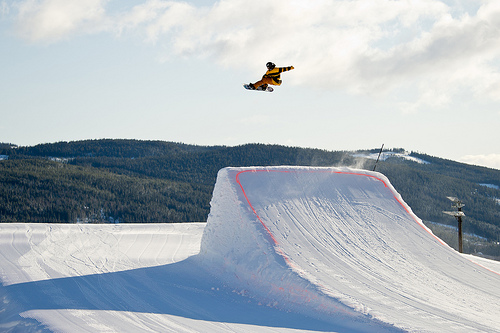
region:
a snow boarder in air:
[241, 60, 294, 91]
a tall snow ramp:
[196, 162, 496, 327]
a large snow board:
[240, 80, 272, 90]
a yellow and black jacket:
[261, 63, 291, 83]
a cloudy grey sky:
[1, 0, 498, 170]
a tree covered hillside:
[0, 139, 499, 259]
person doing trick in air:
[240, 53, 288, 93]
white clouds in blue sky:
[64, 43, 82, 53]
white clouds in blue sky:
[358, 102, 410, 129]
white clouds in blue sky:
[442, 45, 496, 102]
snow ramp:
[225, 162, 455, 317]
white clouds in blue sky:
[141, 18, 185, 53]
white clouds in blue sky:
[138, 72, 173, 96]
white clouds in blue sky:
[362, 29, 403, 66]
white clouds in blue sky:
[54, 81, 76, 88]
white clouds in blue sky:
[112, 56, 147, 86]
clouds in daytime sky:
[0, 1, 499, 165]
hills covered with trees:
[0, 134, 497, 223]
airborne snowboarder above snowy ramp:
[2, 57, 497, 331]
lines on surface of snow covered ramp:
[201, 163, 497, 331]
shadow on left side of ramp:
[3, 166, 492, 329]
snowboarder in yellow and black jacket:
[245, 62, 295, 93]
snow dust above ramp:
[200, 153, 497, 331]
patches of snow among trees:
[364, 145, 497, 254]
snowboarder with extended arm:
[245, 61, 295, 91]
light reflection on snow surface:
[2, 220, 204, 331]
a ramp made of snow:
[207, 160, 494, 328]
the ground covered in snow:
[14, 215, 185, 302]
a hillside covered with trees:
[5, 131, 222, 180]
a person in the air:
[243, 55, 303, 102]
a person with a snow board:
[240, 55, 290, 95]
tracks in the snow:
[23, 218, 159, 292]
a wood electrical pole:
[453, 195, 474, 254]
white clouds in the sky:
[340, 9, 487, 97]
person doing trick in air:
[237, 57, 291, 92]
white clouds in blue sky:
[47, 36, 62, 61]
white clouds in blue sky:
[82, 79, 109, 101]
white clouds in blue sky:
[119, 26, 136, 46]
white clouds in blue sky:
[202, 26, 224, 53]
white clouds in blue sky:
[337, 68, 367, 113]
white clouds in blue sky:
[418, 35, 455, 74]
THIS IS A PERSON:
[251, 50, 291, 102]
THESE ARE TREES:
[36, 171, 73, 208]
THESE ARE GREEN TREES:
[420, 155, 460, 185]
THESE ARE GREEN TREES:
[168, 135, 200, 182]